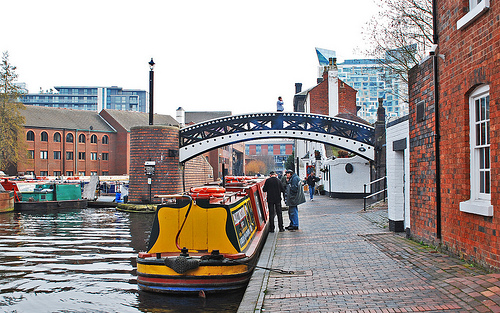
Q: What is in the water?
A: Boats.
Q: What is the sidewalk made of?
A: Bricks.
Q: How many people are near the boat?
A: Two.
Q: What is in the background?
A: A walking bridge.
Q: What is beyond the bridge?
A: Buildings.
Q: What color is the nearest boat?
A: Black and yellow.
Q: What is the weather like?
A: Overcast.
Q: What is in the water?
A: The boats.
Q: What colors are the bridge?
A: Blue and white.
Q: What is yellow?
A: Boat.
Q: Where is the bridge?
A: Over the water.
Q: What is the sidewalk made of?
A: Brick.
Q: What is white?
A: Window.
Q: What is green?
A: A boat.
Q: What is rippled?
A: Water.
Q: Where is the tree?
A: Above the building.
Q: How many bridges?
A: One.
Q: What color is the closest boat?
A: Yellow.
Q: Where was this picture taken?
A: In a city.